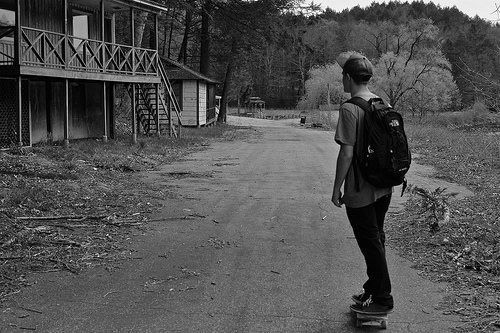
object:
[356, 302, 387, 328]
skateboard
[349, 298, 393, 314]
black shoes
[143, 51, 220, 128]
house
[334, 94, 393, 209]
shirt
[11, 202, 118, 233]
limb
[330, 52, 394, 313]
guy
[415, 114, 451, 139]
ground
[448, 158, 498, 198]
leaves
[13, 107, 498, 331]
ground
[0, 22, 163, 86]
porch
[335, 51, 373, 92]
head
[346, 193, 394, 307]
pants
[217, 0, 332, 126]
tree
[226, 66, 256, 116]
tree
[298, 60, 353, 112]
tree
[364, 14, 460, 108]
tree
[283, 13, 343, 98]
tree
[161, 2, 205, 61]
trees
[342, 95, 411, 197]
pack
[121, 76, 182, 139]
stairs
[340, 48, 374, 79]
cap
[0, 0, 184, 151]
building